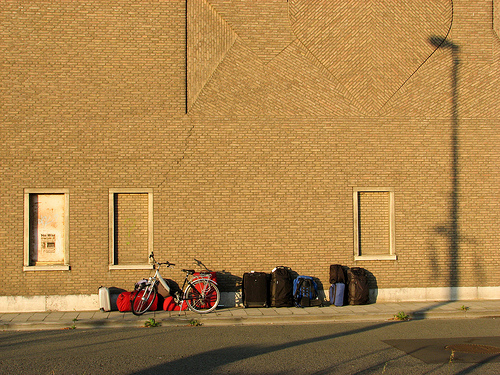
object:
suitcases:
[294, 275, 324, 306]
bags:
[291, 275, 324, 307]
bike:
[127, 251, 220, 316]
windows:
[106, 189, 152, 271]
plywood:
[28, 193, 63, 266]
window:
[23, 185, 69, 271]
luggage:
[241, 272, 271, 308]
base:
[0, 291, 103, 313]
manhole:
[442, 339, 498, 356]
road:
[3, 323, 500, 375]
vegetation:
[145, 318, 159, 326]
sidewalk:
[0, 298, 500, 330]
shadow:
[130, 297, 459, 373]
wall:
[0, 34, 500, 304]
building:
[0, 0, 499, 303]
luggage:
[271, 265, 293, 308]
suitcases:
[328, 282, 346, 307]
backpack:
[294, 275, 319, 306]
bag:
[117, 289, 156, 311]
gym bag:
[163, 297, 188, 311]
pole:
[448, 30, 462, 299]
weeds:
[393, 309, 411, 323]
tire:
[185, 281, 220, 315]